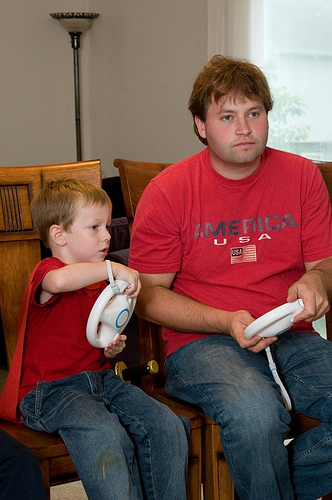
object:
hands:
[228, 308, 278, 353]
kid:
[16, 173, 189, 498]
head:
[187, 54, 274, 166]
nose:
[98, 226, 112, 241]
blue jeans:
[164, 328, 331, 499]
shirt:
[11, 256, 113, 405]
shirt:
[127, 146, 331, 360]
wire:
[265, 346, 293, 409]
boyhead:
[30, 178, 113, 264]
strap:
[104, 258, 116, 285]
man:
[126, 53, 331, 498]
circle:
[115, 308, 129, 329]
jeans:
[19, 367, 191, 499]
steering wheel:
[85, 278, 138, 350]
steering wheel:
[243, 298, 303, 340]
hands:
[111, 260, 141, 298]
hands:
[103, 332, 128, 360]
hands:
[285, 269, 330, 323]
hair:
[187, 53, 273, 147]